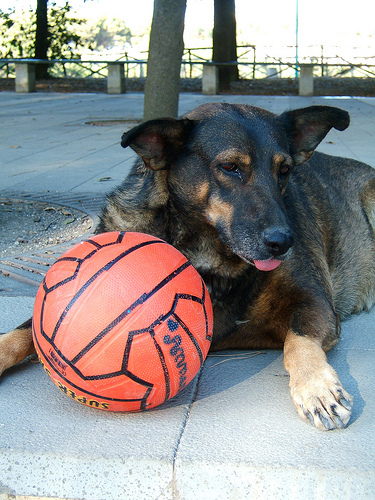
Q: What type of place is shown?
A: It is a sidewalk.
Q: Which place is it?
A: It is a sidewalk.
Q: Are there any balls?
A: Yes, there is a ball.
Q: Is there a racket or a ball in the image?
A: Yes, there is a ball.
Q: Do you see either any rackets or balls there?
A: Yes, there is a ball.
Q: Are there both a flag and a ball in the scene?
A: No, there is a ball but no flags.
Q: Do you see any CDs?
A: No, there are no cds.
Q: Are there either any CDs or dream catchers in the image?
A: No, there are no CDs or dream catchers.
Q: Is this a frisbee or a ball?
A: This is a ball.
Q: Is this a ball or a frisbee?
A: This is a ball.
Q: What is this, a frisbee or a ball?
A: This is a ball.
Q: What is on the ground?
A: The ball is on the ground.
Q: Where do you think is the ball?
A: The ball is on the ground.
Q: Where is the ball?
A: The ball is on the ground.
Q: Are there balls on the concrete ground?
A: Yes, there is a ball on the ground.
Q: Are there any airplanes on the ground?
A: No, there is a ball on the ground.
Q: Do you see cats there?
A: No, there are no cats.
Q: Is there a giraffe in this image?
A: No, there are no giraffes.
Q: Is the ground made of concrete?
A: Yes, the ground is made of concrete.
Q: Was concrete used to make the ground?
A: Yes, the ground is made of concrete.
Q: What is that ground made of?
A: The ground is made of concrete.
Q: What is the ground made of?
A: The ground is made of concrete.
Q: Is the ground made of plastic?
A: No, the ground is made of concrete.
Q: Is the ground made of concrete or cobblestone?
A: The ground is made of concrete.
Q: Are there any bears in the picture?
A: No, there are no bears.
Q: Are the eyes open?
A: Yes, the eyes are open.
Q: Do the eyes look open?
A: Yes, the eyes are open.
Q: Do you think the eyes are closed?
A: No, the eyes are open.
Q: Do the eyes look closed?
A: No, the eyes are open.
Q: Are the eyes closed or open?
A: The eyes are open.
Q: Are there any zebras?
A: No, there are no zebras.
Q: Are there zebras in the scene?
A: No, there are no zebras.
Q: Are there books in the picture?
A: No, there are no books.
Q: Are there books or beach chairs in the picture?
A: No, there are no books or beach chairs.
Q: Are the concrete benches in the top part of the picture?
A: Yes, the benches are in the top of the image.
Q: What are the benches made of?
A: The benches are made of concrete.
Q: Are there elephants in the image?
A: No, there are no elephants.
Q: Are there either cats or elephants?
A: No, there are no elephants or cats.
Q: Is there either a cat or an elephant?
A: No, there are no elephants or cats.